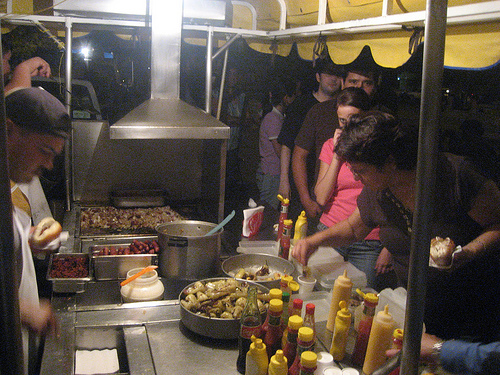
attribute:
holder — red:
[226, 192, 274, 236]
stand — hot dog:
[2, 5, 498, 373]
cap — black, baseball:
[7, 78, 79, 147]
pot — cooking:
[176, 269, 286, 349]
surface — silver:
[41, 267, 244, 373]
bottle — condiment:
[267, 298, 283, 350]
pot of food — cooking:
[147, 210, 242, 283]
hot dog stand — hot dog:
[17, 8, 499, 351]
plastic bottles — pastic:
[232, 269, 435, 373]